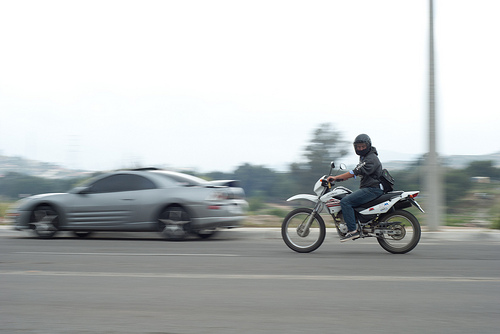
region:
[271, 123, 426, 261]
Man on a motorcycle looking at the camera.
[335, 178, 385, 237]
Man wearing blue jeans.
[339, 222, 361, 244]
Man wearing a pair of sneakers.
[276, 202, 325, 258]
Black tires on the motorcycle.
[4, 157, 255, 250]
Silver car on the road.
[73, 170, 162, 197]
Car with tinted windows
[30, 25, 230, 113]
Light sky high above.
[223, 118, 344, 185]
Trees in the distance.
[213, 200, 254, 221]
License plate on the car.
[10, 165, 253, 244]
a silver two door car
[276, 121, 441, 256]
a man with a black jacket and blue jeans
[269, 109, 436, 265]
a white dirt bike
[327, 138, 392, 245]
a man with a motorcycle helmet on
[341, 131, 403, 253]
a man with a leather backpack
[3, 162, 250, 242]
a car with a sun roof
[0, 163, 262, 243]
a car with black tinted windows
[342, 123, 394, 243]
a man with black and white sneakers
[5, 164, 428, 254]
a car in front of a dirt bike on the road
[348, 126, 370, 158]
man is wearing helmet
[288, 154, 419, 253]
man is riding motorcycle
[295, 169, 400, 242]
a white dirt bike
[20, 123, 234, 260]
a silver blurry car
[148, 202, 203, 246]
car has blurry rim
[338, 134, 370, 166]
man is looking at photographer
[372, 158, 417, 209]
man has black backpack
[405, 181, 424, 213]
license plate on bike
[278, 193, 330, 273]
bike has large tire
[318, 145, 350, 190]
bike has 2 mirrors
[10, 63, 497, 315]
Some traffic is on a roadway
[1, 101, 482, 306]
Some traffic is moving very fast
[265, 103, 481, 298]
A motorbike is on a roadway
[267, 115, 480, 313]
A person is wearing a helmet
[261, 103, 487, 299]
A person is obeying the law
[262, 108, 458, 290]
A person is watching for cars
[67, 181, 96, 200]
Small white side mirror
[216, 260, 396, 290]
Long narrow white line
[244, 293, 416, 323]
Smooth grey road tarmac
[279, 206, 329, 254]
Circular shaped front wheel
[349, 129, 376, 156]
Black colored protective helmet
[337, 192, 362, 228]
Blue fitting jeans pants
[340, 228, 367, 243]
White and black sneakers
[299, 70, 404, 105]
Clear white cloudless sky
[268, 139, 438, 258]
man on an offroad motorcycle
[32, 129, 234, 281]
the car is blurry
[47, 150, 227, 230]
the car is silver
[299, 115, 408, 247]
this is a man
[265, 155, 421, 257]
the bike is white and black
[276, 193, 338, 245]
the wheel is black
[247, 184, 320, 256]
the tire is rubber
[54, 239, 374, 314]
this is a highway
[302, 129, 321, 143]
laves on the tree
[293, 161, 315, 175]
laves on the tree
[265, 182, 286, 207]
laves on the tree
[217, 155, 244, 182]
leaves on the tree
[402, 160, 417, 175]
leaves on the tree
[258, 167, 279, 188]
leaves on the tree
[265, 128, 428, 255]
motor bike on the road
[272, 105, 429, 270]
woman riding a bike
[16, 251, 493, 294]
line on the road